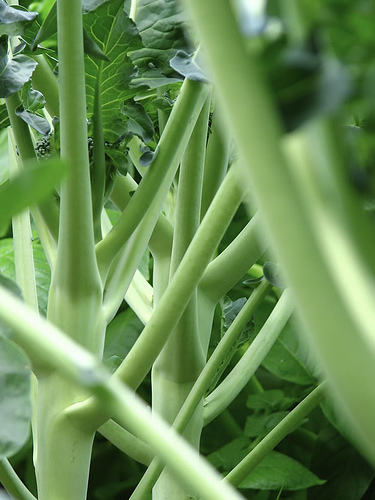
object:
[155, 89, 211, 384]
stalk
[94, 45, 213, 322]
stalk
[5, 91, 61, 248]
stalk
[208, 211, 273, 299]
stem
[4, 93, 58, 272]
stem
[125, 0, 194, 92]
broccoli leaf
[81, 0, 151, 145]
leaf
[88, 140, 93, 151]
flower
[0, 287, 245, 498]
stem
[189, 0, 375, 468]
stem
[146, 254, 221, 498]
stem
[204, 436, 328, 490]
celery leafs(broccoli)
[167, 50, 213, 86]
leaf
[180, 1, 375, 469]
plant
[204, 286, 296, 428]
stalk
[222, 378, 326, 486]
stem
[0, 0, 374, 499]
banana tree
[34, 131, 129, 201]
broccoli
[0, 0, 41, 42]
broccoli leaf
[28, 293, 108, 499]
stem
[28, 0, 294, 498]
tree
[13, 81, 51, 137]
banana leaf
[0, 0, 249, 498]
plant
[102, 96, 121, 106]
vein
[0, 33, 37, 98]
leaf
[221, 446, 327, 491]
leaf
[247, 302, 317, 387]
leaf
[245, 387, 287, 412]
leaf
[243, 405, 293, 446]
leaf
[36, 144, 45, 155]
flower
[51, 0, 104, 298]
stem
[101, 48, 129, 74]
veins